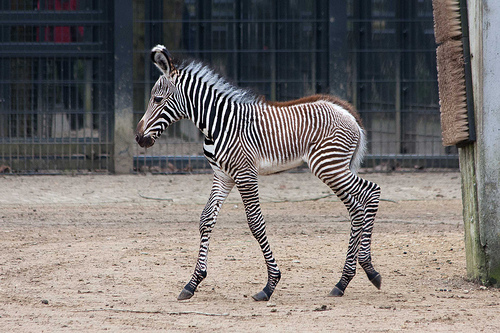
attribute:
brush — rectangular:
[433, 5, 474, 144]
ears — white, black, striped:
[148, 43, 171, 79]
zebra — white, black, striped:
[136, 45, 381, 300]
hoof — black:
[176, 287, 194, 300]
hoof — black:
[249, 290, 269, 302]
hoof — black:
[326, 285, 346, 299]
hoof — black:
[368, 273, 385, 293]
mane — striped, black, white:
[183, 61, 260, 112]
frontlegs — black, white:
[172, 180, 282, 300]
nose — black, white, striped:
[133, 111, 155, 150]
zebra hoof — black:
[132, 39, 387, 305]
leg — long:
[231, 179, 286, 306]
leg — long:
[173, 172, 232, 300]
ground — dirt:
[56, 219, 196, 289]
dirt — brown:
[0, 172, 498, 330]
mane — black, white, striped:
[177, 57, 268, 109]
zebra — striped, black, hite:
[113, 68, 477, 309]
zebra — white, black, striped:
[111, 35, 435, 312]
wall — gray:
[465, 0, 498, 292]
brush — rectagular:
[427, 0, 479, 151]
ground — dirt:
[54, 214, 196, 291]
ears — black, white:
[155, 39, 187, 81]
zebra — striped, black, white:
[115, 45, 394, 302]